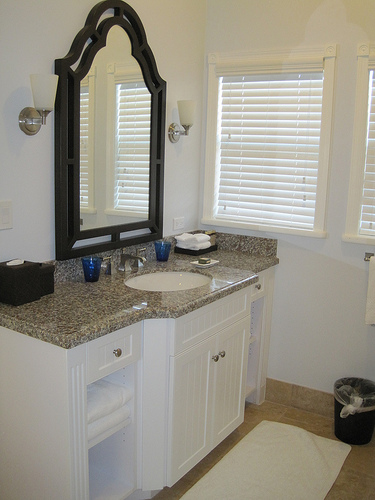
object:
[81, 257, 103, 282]
blue cup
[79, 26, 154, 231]
mirror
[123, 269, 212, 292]
sink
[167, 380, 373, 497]
floor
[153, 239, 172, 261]
blue glass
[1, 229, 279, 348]
counter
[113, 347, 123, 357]
handle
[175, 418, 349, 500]
mat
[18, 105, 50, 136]
sconses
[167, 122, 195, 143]
sconses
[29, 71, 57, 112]
fixture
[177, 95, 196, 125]
fixture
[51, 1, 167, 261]
frame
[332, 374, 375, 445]
wastebasket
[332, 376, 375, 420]
clear bag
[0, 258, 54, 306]
holder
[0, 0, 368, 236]
interior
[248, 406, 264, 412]
line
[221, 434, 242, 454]
line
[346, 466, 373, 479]
line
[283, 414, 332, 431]
line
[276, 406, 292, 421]
line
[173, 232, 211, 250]
towels